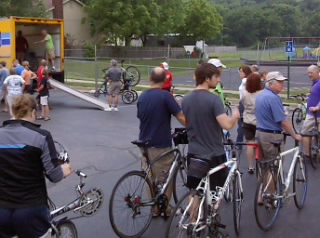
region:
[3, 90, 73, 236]
This is a person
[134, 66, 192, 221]
This is a person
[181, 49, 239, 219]
This is a person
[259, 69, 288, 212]
This is a person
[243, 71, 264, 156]
This is a person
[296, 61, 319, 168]
This is a person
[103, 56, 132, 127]
This is a person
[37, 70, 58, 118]
This is a person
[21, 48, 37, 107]
This is a person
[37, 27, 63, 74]
This is a person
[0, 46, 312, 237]
people with bikes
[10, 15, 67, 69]
guy loading a truck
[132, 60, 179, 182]
guy with a hair bald spot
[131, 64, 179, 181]
guy wearing a blue shirt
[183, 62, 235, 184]
guy with the grey shirt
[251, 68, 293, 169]
guy wearing a white shirt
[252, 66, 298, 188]
guy wearing a belt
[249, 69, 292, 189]
guy wearing beige shorts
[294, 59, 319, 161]
guy wearing a purple shirt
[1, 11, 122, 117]
ramp to the truck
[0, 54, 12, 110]
This is a person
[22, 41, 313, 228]
Several different types of bicycles.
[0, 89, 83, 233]
Lady with brown hair in pony tail.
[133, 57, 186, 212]
Middle age man that is going bald.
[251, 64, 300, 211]
Older gentleman with short sleeve blue shirt.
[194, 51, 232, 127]
Person with lime green shirt on.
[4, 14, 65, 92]
Yellow moving truck to load bicycles on.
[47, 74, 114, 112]
Gray aluminum ramp for loading bicycles.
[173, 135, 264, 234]
White bicycle with black and red handlebar.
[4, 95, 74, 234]
Lady in shorts so pants will not get caught in bicycle.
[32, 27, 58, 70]
Man in lime green shirt giving instructions.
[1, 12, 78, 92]
a yellow moving truck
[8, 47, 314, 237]
a group of people with bicycles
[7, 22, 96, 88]
men loading things onto a truck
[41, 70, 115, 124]
a ramp to load things up a truck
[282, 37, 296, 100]
a handicap parking sign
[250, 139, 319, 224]
a white bicycle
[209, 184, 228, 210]
a water bottle holder on a bicycle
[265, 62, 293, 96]
a man wearing a baseball cap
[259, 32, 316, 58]
a swing set in a park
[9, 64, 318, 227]
a group of people in a parking lot with bicycles